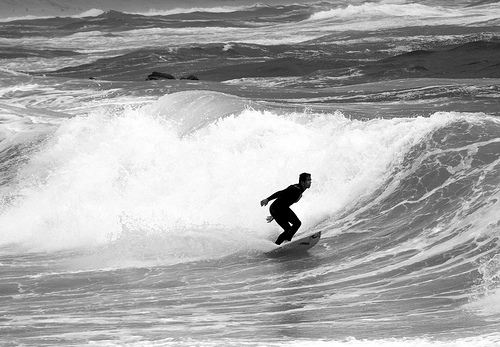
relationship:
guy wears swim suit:
[260, 172, 312, 245] [264, 185, 307, 234]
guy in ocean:
[260, 172, 312, 245] [193, 100, 403, 312]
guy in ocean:
[260, 172, 312, 245] [213, 98, 402, 301]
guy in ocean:
[260, 172, 312, 245] [197, 87, 400, 305]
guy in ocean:
[260, 172, 312, 245] [202, 56, 434, 308]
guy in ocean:
[260, 172, 312, 245] [182, 80, 414, 309]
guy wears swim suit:
[260, 172, 312, 245] [266, 184, 307, 245]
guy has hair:
[260, 172, 312, 245] [295, 169, 313, 189]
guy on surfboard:
[260, 172, 312, 245] [261, 218, 326, 263]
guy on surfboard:
[260, 172, 312, 245] [266, 224, 327, 262]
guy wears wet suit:
[260, 172, 312, 245] [262, 182, 307, 242]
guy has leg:
[260, 172, 312, 245] [273, 209, 296, 247]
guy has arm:
[260, 172, 312, 245] [255, 184, 287, 209]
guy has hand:
[260, 172, 312, 245] [253, 194, 274, 212]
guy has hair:
[257, 165, 318, 250] [293, 167, 314, 190]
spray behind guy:
[0, 99, 469, 267] [260, 172, 312, 245]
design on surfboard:
[297, 233, 320, 256] [268, 227, 324, 263]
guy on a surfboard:
[260, 172, 312, 245] [265, 228, 320, 255]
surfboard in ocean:
[262, 231, 320, 258] [0, 0, 499, 346]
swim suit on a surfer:
[266, 184, 307, 245] [264, 170, 317, 250]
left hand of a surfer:
[264, 212, 276, 223] [264, 171, 318, 239]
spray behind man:
[0, 99, 469, 267] [261, 170, 311, 250]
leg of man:
[275, 216, 293, 244] [261, 170, 311, 250]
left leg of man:
[288, 210, 306, 242] [260, 164, 310, 253]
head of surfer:
[301, 174, 312, 188] [260, 169, 310, 248]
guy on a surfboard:
[260, 172, 312, 245] [271, 229, 320, 254]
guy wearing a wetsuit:
[260, 172, 312, 245] [274, 180, 306, 237]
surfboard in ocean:
[260, 231, 320, 253] [0, 0, 499, 346]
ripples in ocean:
[125, 24, 498, 114] [0, 0, 499, 346]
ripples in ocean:
[0, 7, 499, 162] [0, 0, 499, 346]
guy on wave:
[260, 172, 312, 245] [5, 102, 493, 302]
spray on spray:
[32, 100, 413, 251] [0, 99, 469, 267]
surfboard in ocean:
[262, 231, 320, 258] [2, 3, 492, 344]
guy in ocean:
[260, 172, 312, 245] [0, 0, 499, 346]